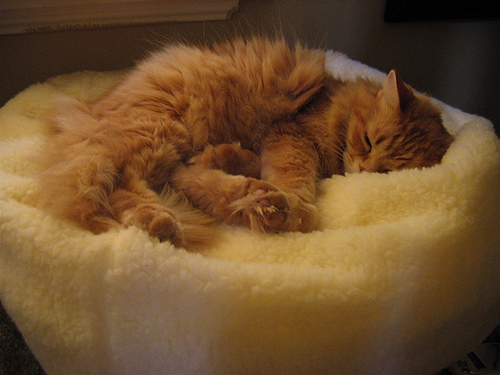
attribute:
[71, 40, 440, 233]
cat — orange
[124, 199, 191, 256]
paw — tan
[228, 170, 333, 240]
paw — tan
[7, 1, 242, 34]
window — painted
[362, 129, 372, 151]
eye — closed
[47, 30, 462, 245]
cat — sleeping, orange, cute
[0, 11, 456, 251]
cat — tan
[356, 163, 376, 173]
nose — tan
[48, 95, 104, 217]
tail — tan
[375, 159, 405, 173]
eye — closed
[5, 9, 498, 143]
wall — brown